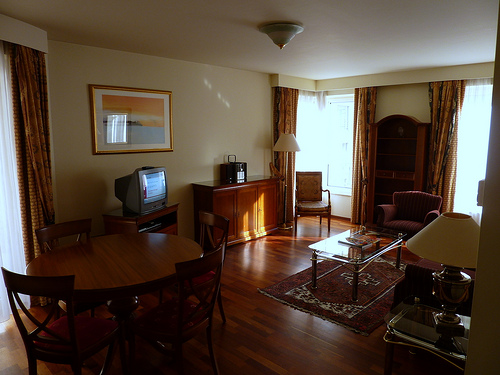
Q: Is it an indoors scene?
A: Yes, it is indoors.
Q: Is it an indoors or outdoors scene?
A: It is indoors.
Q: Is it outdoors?
A: No, it is indoors.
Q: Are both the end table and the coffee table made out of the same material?
A: Yes, both the end table and the coffee table are made of glass.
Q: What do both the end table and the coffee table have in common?
A: The material, both the end table and the coffee table are glass.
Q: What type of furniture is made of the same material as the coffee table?
A: The end table is made of the same material as the coffee table.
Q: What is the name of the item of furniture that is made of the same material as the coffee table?
A: The piece of furniture is an end table.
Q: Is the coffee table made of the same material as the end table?
A: Yes, both the coffee table and the end table are made of glass.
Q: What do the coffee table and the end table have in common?
A: The material, both the coffee table and the end table are glass.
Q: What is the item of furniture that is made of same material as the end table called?
A: The piece of furniture is a coffee table.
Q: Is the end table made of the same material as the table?
A: No, the end table is made of glass and the table is made of wood.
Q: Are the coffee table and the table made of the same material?
A: No, the coffee table is made of glass and the table is made of wood.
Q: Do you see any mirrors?
A: No, there are no mirrors.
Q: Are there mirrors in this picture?
A: No, there are no mirrors.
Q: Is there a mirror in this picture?
A: No, there are no mirrors.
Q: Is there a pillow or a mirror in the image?
A: No, there are no mirrors or pillows.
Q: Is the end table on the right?
A: Yes, the end table is on the right of the image.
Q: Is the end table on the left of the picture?
A: No, the end table is on the right of the image.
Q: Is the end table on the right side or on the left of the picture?
A: The end table is on the right of the image.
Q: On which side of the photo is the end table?
A: The end table is on the right of the image.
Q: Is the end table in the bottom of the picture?
A: Yes, the end table is in the bottom of the image.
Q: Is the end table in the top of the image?
A: No, the end table is in the bottom of the image.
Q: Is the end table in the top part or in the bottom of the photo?
A: The end table is in the bottom of the image.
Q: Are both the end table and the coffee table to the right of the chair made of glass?
A: Yes, both the end table and the coffee table are made of glass.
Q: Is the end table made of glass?
A: Yes, the end table is made of glass.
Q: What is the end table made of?
A: The end table is made of glass.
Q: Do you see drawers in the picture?
A: No, there are no drawers.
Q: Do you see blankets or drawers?
A: No, there are no drawers or blankets.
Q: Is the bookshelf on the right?
A: Yes, the bookshelf is on the right of the image.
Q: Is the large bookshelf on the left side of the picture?
A: No, the bookshelf is on the right of the image.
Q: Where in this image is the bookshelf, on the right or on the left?
A: The bookshelf is on the right of the image.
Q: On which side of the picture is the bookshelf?
A: The bookshelf is on the right of the image.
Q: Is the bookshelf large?
A: Yes, the bookshelf is large.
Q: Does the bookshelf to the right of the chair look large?
A: Yes, the bookshelf is large.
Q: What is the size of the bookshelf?
A: The bookshelf is large.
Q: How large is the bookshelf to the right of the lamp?
A: The bookshelf is large.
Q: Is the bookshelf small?
A: No, the bookshelf is large.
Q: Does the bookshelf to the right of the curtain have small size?
A: No, the bookshelf is large.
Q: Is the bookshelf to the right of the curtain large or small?
A: The bookshelf is large.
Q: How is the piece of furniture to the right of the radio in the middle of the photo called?
A: The piece of furniture is a bookshelf.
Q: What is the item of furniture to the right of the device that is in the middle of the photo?
A: The piece of furniture is a bookshelf.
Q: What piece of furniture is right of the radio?
A: The piece of furniture is a bookshelf.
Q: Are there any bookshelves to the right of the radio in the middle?
A: Yes, there is a bookshelf to the right of the radio.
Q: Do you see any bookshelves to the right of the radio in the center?
A: Yes, there is a bookshelf to the right of the radio.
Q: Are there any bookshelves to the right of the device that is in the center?
A: Yes, there is a bookshelf to the right of the radio.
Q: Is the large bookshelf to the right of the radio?
A: Yes, the bookshelf is to the right of the radio.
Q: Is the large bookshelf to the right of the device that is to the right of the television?
A: Yes, the bookshelf is to the right of the radio.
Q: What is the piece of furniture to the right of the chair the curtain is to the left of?
A: The piece of furniture is a bookshelf.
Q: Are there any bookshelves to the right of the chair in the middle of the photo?
A: Yes, there is a bookshelf to the right of the chair.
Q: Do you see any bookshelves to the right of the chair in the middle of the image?
A: Yes, there is a bookshelf to the right of the chair.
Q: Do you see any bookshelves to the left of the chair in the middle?
A: No, the bookshelf is to the right of the chair.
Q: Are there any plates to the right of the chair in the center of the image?
A: No, there is a bookshelf to the right of the chair.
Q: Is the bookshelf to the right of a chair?
A: Yes, the bookshelf is to the right of a chair.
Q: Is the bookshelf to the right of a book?
A: No, the bookshelf is to the right of a chair.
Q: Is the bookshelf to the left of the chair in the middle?
A: No, the bookshelf is to the right of the chair.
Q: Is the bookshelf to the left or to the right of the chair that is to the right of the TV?
A: The bookshelf is to the right of the chair.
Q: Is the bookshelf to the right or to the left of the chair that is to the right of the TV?
A: The bookshelf is to the right of the chair.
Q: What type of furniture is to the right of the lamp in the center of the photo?
A: The piece of furniture is a bookshelf.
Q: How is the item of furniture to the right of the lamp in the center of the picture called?
A: The piece of furniture is a bookshelf.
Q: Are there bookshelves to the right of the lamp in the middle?
A: Yes, there is a bookshelf to the right of the lamp.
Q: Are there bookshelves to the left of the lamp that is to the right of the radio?
A: No, the bookshelf is to the right of the lamp.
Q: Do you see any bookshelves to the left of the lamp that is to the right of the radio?
A: No, the bookshelf is to the right of the lamp.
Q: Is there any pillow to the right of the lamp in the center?
A: No, there is a bookshelf to the right of the lamp.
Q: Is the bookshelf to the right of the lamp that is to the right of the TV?
A: Yes, the bookshelf is to the right of the lamp.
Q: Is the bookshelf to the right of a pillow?
A: No, the bookshelf is to the right of the lamp.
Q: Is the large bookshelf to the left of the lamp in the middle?
A: No, the bookshelf is to the right of the lamp.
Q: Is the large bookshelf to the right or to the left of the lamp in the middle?
A: The bookshelf is to the right of the lamp.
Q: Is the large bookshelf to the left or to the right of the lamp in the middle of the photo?
A: The bookshelf is to the right of the lamp.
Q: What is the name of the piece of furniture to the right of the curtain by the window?
A: The piece of furniture is a bookshelf.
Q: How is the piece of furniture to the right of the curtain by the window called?
A: The piece of furniture is a bookshelf.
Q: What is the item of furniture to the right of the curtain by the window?
A: The piece of furniture is a bookshelf.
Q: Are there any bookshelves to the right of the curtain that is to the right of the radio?
A: Yes, there is a bookshelf to the right of the curtain.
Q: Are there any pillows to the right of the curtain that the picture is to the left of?
A: No, there is a bookshelf to the right of the curtain.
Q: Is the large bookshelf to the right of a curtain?
A: Yes, the bookshelf is to the right of a curtain.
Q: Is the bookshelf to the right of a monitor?
A: No, the bookshelf is to the right of a curtain.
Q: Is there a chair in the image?
A: Yes, there is a chair.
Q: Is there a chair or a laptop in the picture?
A: Yes, there is a chair.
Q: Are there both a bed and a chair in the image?
A: No, there is a chair but no beds.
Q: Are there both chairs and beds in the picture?
A: No, there is a chair but no beds.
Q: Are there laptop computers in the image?
A: No, there are no laptop computers.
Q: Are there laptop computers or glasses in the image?
A: No, there are no laptop computers or glasses.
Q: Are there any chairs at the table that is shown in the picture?
A: Yes, there is a chair at the table.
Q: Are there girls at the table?
A: No, there is a chair at the table.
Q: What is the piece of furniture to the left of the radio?
A: The piece of furniture is a chair.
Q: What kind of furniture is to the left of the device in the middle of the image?
A: The piece of furniture is a chair.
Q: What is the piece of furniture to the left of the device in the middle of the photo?
A: The piece of furniture is a chair.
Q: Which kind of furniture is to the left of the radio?
A: The piece of furniture is a chair.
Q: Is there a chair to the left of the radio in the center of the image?
A: Yes, there is a chair to the left of the radio.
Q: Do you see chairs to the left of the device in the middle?
A: Yes, there is a chair to the left of the radio.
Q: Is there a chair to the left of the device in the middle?
A: Yes, there is a chair to the left of the radio.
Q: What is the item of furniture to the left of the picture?
A: The piece of furniture is a chair.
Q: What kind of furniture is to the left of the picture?
A: The piece of furniture is a chair.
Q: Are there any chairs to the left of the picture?
A: Yes, there is a chair to the left of the picture.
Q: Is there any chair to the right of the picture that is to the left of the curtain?
A: No, the chair is to the left of the picture.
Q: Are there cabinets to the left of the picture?
A: No, there is a chair to the left of the picture.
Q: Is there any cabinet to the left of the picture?
A: No, there is a chair to the left of the picture.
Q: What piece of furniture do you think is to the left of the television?
A: The piece of furniture is a chair.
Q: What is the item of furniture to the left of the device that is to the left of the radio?
A: The piece of furniture is a chair.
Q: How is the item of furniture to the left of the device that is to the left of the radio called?
A: The piece of furniture is a chair.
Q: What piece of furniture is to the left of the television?
A: The piece of furniture is a chair.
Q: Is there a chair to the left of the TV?
A: Yes, there is a chair to the left of the TV.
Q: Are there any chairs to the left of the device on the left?
A: Yes, there is a chair to the left of the TV.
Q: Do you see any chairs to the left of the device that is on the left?
A: Yes, there is a chair to the left of the TV.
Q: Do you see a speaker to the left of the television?
A: No, there is a chair to the left of the television.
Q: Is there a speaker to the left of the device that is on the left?
A: No, there is a chair to the left of the television.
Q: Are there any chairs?
A: Yes, there is a chair.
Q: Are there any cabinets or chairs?
A: Yes, there is a chair.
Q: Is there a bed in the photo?
A: No, there are no beds.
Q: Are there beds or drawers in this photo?
A: No, there are no beds or drawers.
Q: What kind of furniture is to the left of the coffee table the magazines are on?
A: The piece of furniture is a chair.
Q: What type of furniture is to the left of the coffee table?
A: The piece of furniture is a chair.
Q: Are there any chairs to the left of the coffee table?
A: Yes, there is a chair to the left of the coffee table.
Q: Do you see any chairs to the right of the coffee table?
A: No, the chair is to the left of the coffee table.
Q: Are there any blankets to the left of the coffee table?
A: No, there is a chair to the left of the coffee table.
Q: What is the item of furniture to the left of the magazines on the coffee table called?
A: The piece of furniture is a chair.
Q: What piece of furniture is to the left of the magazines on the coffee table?
A: The piece of furniture is a chair.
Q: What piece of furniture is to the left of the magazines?
A: The piece of furniture is a chair.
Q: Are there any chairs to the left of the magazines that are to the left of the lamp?
A: Yes, there is a chair to the left of the magazines.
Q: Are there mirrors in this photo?
A: No, there are no mirrors.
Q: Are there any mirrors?
A: No, there are no mirrors.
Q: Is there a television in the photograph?
A: Yes, there is a television.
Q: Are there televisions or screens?
A: Yes, there is a television.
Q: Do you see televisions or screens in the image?
A: Yes, there is a television.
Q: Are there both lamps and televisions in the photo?
A: Yes, there are both a television and a lamp.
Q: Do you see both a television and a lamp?
A: Yes, there are both a television and a lamp.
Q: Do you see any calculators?
A: No, there are no calculators.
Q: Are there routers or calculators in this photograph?
A: No, there are no calculators or routers.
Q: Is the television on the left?
A: Yes, the television is on the left of the image.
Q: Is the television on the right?
A: No, the television is on the left of the image.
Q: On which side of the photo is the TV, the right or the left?
A: The TV is on the left of the image.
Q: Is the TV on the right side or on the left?
A: The TV is on the left of the image.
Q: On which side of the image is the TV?
A: The TV is on the left of the image.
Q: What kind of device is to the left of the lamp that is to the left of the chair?
A: The device is a television.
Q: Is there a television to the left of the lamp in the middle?
A: Yes, there is a television to the left of the lamp.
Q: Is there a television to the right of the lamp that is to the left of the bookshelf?
A: No, the television is to the left of the lamp.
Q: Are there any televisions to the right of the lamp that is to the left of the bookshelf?
A: No, the television is to the left of the lamp.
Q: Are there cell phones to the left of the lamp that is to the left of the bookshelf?
A: No, there is a television to the left of the lamp.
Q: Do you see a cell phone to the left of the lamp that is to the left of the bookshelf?
A: No, there is a television to the left of the lamp.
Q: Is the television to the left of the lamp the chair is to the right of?
A: Yes, the television is to the left of the lamp.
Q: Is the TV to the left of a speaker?
A: No, the TV is to the left of the lamp.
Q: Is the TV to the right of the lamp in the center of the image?
A: No, the TV is to the left of the lamp.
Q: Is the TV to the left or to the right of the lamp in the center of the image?
A: The TV is to the left of the lamp.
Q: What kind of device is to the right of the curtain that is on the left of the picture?
A: The device is a television.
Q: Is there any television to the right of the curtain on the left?
A: Yes, there is a television to the right of the curtain.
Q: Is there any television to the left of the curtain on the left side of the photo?
A: No, the television is to the right of the curtain.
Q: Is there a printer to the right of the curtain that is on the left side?
A: No, there is a television to the right of the curtain.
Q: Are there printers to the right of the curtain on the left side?
A: No, there is a television to the right of the curtain.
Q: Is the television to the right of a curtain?
A: Yes, the television is to the right of a curtain.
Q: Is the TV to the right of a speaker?
A: No, the TV is to the right of a curtain.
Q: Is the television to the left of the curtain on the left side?
A: No, the television is to the right of the curtain.